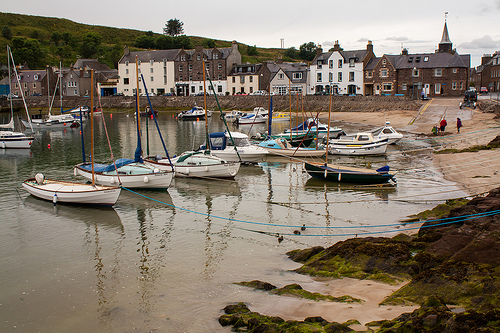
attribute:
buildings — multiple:
[114, 11, 498, 129]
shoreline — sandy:
[196, 101, 499, 216]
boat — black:
[297, 156, 398, 188]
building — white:
[301, 40, 372, 94]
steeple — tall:
[421, 9, 495, 64]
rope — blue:
[119, 183, 499, 231]